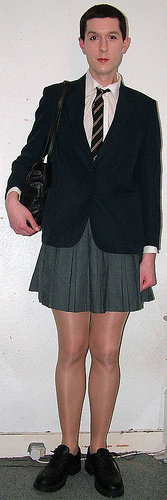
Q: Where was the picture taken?
A: In front of a wall.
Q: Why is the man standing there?
A: To take a picture.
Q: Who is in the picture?
A: A man.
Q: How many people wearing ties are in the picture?
A: One.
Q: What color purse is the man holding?
A: Black.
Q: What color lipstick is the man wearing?
A: Red.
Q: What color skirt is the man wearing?
A: Gray.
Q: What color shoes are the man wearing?
A: Black.